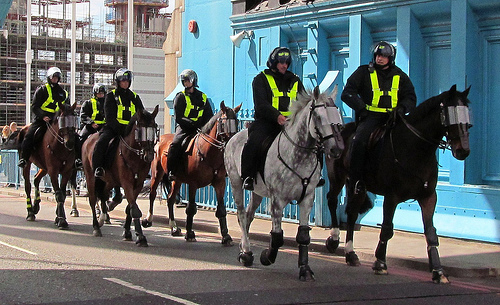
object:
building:
[163, 0, 498, 247]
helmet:
[370, 39, 396, 68]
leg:
[258, 197, 286, 267]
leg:
[225, 176, 260, 267]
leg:
[239, 189, 267, 240]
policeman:
[339, 46, 419, 173]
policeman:
[94, 69, 154, 179]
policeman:
[24, 67, 71, 163]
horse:
[13, 98, 81, 231]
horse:
[140, 99, 245, 248]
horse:
[80, 103, 165, 248]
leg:
[184, 185, 198, 242]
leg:
[213, 177, 237, 246]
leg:
[419, 190, 449, 285]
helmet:
[113, 66, 135, 90]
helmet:
[267, 46, 294, 77]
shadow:
[1, 210, 498, 303]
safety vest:
[358, 67, 410, 119]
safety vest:
[260, 69, 307, 123]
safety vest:
[176, 89, 209, 127]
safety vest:
[107, 92, 144, 130]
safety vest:
[81, 95, 107, 130]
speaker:
[226, 29, 256, 50]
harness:
[271, 90, 343, 207]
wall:
[157, 0, 500, 246]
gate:
[162, 106, 331, 229]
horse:
[222, 82, 347, 282]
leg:
[296, 192, 313, 283]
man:
[239, 47, 309, 191]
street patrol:
[18, 41, 420, 196]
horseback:
[327, 120, 419, 168]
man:
[164, 71, 216, 201]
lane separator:
[0, 239, 40, 255]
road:
[0, 188, 496, 302]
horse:
[323, 83, 473, 285]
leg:
[371, 197, 401, 275]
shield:
[115, 68, 133, 78]